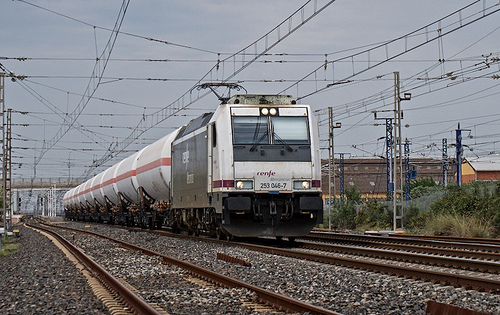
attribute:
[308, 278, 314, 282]
stone — black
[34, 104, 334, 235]
train — white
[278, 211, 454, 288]
tracks — brown train 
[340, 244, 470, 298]
tracks — train, couple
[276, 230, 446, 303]
tracks — gravel 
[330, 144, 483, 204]
building — background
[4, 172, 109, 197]
bridge — background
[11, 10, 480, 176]
wires — electric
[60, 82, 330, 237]
train — red, white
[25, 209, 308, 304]
tracks — train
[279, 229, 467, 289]
tracks — train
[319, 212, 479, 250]
tracks — train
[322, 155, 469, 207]
building — red, brick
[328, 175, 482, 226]
bushes — green, leafy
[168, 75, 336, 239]
car — train, engine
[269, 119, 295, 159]
wipers — windshield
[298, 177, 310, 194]
headlight — white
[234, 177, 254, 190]
headlight — white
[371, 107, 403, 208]
pole — blue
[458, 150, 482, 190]
building — orange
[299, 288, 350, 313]
stones — black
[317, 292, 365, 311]
stones — black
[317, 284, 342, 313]
stones — black